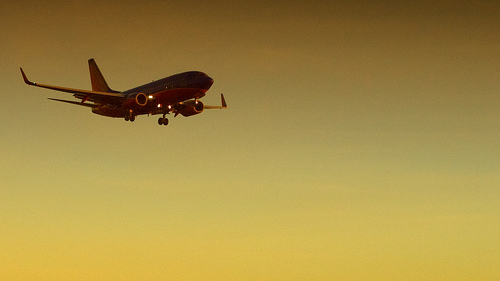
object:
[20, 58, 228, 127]
airplane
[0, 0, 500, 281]
sky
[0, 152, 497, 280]
sunset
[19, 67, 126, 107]
wing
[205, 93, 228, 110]
wing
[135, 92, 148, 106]
jet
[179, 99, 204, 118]
jet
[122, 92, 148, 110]
engine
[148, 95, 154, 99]
lights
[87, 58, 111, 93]
tail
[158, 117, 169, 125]
wheels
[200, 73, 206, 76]
windshield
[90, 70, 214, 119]
body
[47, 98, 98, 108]
flap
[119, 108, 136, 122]
tires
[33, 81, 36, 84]
light